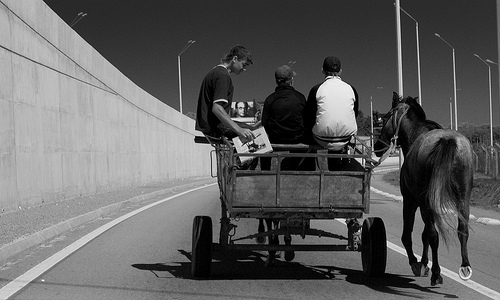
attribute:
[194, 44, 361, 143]
people — three, enjoying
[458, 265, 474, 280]
horse shoe — metal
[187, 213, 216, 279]
wheel — black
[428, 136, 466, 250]
tail — long, silky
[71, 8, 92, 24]
street light — over